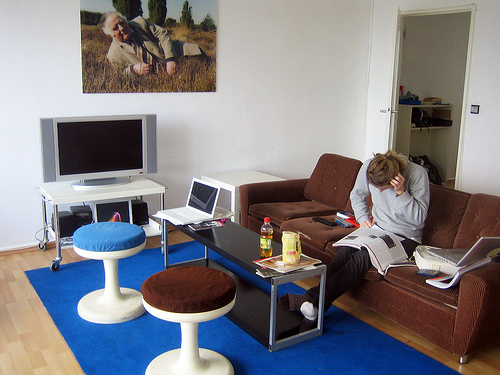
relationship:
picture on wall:
[76, 15, 250, 84] [77, 5, 219, 98]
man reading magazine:
[284, 147, 430, 321] [323, 221, 415, 278]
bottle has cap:
[258, 214, 274, 268] [262, 217, 270, 223]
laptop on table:
[156, 178, 223, 234] [152, 198, 333, 356]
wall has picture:
[7, 5, 365, 136] [77, 5, 219, 98]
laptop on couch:
[156, 178, 223, 234] [245, 147, 497, 364]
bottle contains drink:
[258, 214, 274, 268] [261, 231, 271, 254]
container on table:
[279, 226, 303, 268] [152, 198, 333, 356]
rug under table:
[37, 260, 73, 315] [152, 198, 333, 356]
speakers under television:
[53, 203, 156, 236] [35, 112, 161, 185]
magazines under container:
[251, 250, 325, 278] [279, 226, 303, 268]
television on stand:
[35, 112, 161, 185] [26, 178, 190, 259]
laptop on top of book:
[429, 232, 498, 291] [427, 259, 490, 315]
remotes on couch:
[312, 203, 356, 236] [245, 147, 497, 364]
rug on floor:
[37, 260, 73, 315] [7, 261, 42, 371]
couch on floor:
[245, 147, 497, 364] [7, 261, 42, 371]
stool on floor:
[139, 261, 250, 369] [7, 261, 42, 371]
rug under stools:
[37, 260, 73, 315] [69, 217, 235, 371]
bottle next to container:
[258, 214, 274, 268] [279, 226, 303, 268]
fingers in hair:
[391, 168, 408, 201] [355, 152, 406, 190]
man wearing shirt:
[352, 143, 424, 285] [346, 187, 423, 252]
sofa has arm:
[245, 147, 497, 364] [235, 171, 308, 222]